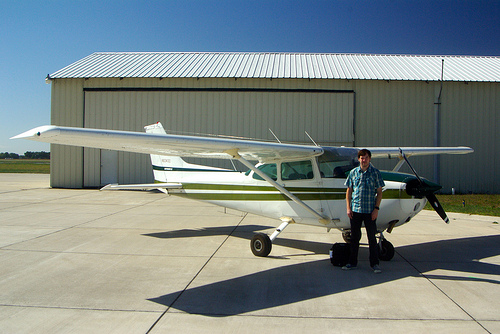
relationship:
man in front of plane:
[331, 145, 384, 275] [29, 102, 471, 275]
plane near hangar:
[29, 102, 471, 275] [54, 43, 492, 191]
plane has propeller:
[29, 102, 471, 275] [407, 160, 445, 218]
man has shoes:
[331, 145, 384, 275] [340, 260, 380, 275]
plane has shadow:
[29, 102, 471, 275] [177, 219, 495, 297]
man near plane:
[331, 145, 384, 275] [29, 102, 471, 275]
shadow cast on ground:
[177, 219, 495, 297] [36, 193, 495, 331]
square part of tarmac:
[200, 247, 428, 313] [2, 188, 158, 244]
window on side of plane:
[253, 159, 318, 181] [29, 102, 471, 275]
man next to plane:
[331, 145, 384, 275] [29, 102, 471, 275]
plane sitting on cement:
[29, 102, 471, 275] [37, 210, 168, 319]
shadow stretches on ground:
[177, 219, 495, 297] [36, 193, 495, 331]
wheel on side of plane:
[241, 228, 273, 263] [29, 102, 471, 275]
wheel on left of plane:
[379, 225, 394, 260] [29, 102, 471, 275]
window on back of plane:
[253, 159, 318, 181] [29, 102, 471, 275]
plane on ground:
[29, 102, 471, 275] [36, 193, 495, 331]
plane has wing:
[29, 102, 471, 275] [18, 121, 317, 202]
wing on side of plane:
[332, 144, 478, 160] [29, 102, 471, 275]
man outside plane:
[331, 145, 384, 275] [29, 102, 471, 275]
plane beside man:
[29, 102, 471, 275] [331, 145, 384, 275]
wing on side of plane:
[18, 121, 317, 202] [29, 102, 471, 275]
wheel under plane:
[241, 228, 273, 263] [29, 102, 471, 275]